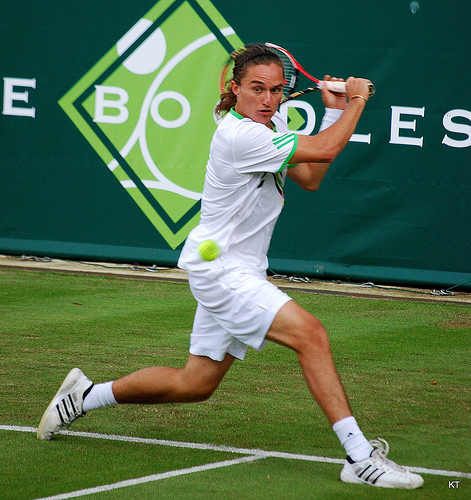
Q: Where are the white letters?
A: Sign.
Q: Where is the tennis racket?
A: Hand.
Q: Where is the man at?
A: Tennis court.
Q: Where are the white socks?
A: Man's legs.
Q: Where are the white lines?
A: Grass.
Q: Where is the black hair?
A: Head.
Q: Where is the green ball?
A: In air.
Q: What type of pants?
A: Shorts.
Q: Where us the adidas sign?
A: Socks.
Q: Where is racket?
A: Hand.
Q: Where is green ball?
A: In air.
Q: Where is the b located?
A: On green wall.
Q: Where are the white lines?
A: Grass.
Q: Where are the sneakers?
A: Feet.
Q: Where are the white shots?
A: On man.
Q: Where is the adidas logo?
A: Socks.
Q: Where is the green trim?
A: On shirt.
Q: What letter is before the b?
A: E.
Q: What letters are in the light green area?
A: Bo.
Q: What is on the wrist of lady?
A: Jewelry.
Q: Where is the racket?
A: In hands.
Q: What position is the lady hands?
A: Swinging.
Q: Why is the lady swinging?
A: Playing tennis.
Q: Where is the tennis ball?
A: In the air.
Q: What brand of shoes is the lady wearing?
A: Adidas.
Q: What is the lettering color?
A: White.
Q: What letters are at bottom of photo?
A: KT.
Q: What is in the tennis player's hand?
A: Tennis racquet.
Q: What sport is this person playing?
A: Tennis.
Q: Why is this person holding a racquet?
A: To play tennis.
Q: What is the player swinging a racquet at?
A: Tennis ball.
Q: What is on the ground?
A: Grass.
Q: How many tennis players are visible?
A: One.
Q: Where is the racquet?
A: In the player's hands.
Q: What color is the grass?
A: Green.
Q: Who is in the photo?
A: The tennis player.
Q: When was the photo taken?
A: During the match.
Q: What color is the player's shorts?
A: White.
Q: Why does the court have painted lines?
A: For boundaries.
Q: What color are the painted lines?
A: White.